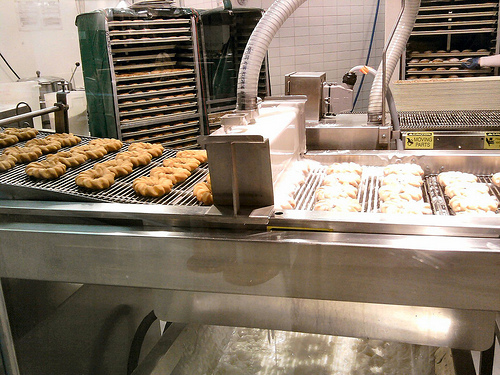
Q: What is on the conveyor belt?
A: Donuts.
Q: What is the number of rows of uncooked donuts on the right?
A: 4.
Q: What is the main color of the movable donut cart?
A: Green.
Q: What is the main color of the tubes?
A: White.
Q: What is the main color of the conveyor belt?
A: Silver.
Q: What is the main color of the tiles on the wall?
A: White.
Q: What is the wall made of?
A: Tiles.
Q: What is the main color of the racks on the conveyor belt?
A: Silver.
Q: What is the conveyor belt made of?
A: Metal.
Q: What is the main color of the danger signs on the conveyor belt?
A: Yellow.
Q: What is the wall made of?
A: White tiles.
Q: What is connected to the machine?
A: Hoses.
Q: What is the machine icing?
A: Crullers.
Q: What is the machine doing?
A: Icing the crullers.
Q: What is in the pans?
A: Doughnuts.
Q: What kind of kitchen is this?
A: Bakery.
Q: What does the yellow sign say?
A: Moving Parts.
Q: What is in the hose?
A: Glazing for doughnuts.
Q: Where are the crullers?
A: On the roller.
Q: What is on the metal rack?
A: Donuts.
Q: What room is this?
A: An industrial kitchen.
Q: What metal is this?
A: Stainless steel.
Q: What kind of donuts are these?
A: Krullers.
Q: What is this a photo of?
A: Doughnut assembly line.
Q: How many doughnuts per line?
A: Four.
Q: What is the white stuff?
A: Powdered sugar.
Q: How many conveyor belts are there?
A: One.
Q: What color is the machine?
A: Silver.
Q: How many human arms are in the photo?
A: One.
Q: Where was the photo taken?
A: At the bakery.